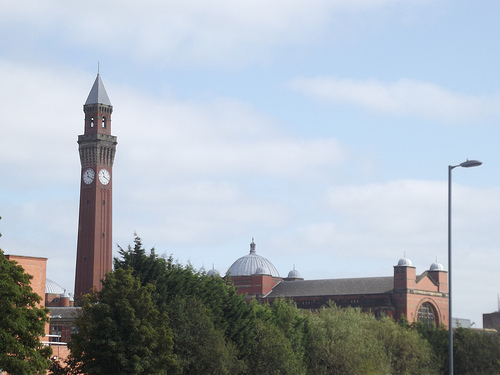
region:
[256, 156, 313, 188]
part of a cloud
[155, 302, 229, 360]
part of a tree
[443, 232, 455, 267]
part of a post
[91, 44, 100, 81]
part of a tip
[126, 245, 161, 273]
top of a bush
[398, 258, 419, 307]
edge of a church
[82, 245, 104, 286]
edge of a tower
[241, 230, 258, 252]
tip of the church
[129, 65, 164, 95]
part of the sky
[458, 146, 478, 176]
part of a lamp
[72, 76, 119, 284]
this is a church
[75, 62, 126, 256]
the church is tall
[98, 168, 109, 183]
clock is on the church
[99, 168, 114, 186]
the clock is white in color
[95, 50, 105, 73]
this is an antennae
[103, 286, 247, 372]
trees are outside the church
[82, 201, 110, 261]
the wall is brown in color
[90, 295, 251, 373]
the leaves are green in color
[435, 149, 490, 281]
this is a street light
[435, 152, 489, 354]
the post is tall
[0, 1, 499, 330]
The sky is blue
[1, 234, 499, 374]
The trees are green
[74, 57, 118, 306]
The clock tower is taller than any other building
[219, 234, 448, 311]
Building has several domes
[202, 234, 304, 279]
One dome is larger than the rest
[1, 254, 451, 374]
Many of the buildings are made of brick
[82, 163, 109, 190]
Two clocks on the tower can be seen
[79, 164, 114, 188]
The clocks are analog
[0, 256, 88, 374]
The bricks are red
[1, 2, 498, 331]
The clouds are white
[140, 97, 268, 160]
white clouds in the sky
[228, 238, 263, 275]
glass dome on a brick building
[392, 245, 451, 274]
small white domes on a building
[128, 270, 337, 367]
green trees lines against the buildings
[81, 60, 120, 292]
red brick steeple on a church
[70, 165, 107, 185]
clock on a brick tower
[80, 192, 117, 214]
windows in the tower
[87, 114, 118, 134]
gazebo on the tower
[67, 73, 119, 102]
steepled roof on top of the tower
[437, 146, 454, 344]
street light on a metal pole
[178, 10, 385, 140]
this is the sky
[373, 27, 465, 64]
the sky is blue in color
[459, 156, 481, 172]
this is a lump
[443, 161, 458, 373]
this is a pole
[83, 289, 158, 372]
this is a tree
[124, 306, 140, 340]
the tree has green leaves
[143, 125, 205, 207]
these are the clouds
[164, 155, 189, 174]
the clouds are white in color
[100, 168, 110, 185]
this is a clock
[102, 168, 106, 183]
the clock is round in shape